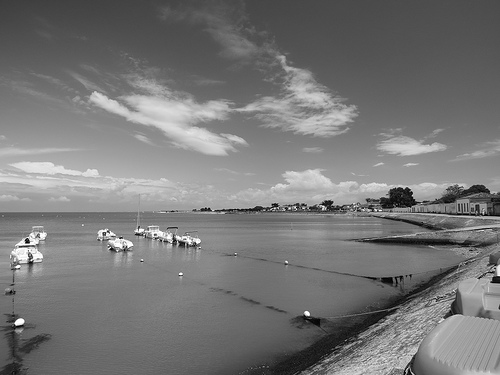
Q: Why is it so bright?
A: Sunny.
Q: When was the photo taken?
A: Day time.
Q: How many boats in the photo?
A: Seven.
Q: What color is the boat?
A: White.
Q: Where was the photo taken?
A: Near water.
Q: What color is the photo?
A: Gray.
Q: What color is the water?
A: Dark.